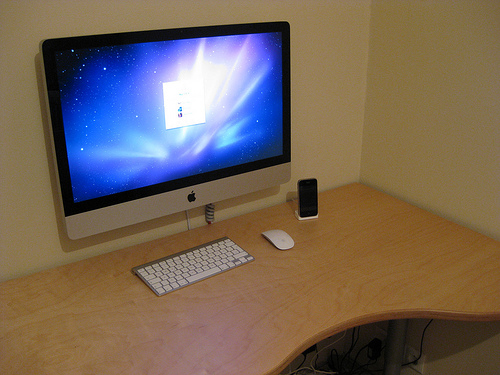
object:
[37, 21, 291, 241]
computer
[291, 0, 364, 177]
wall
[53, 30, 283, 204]
screen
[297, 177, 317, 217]
cellphone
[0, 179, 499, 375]
desk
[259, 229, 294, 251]
mouse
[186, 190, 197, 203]
logo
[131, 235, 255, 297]
keyboard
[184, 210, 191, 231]
wire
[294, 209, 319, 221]
dock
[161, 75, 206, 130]
message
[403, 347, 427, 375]
outlet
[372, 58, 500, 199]
wall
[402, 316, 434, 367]
cord